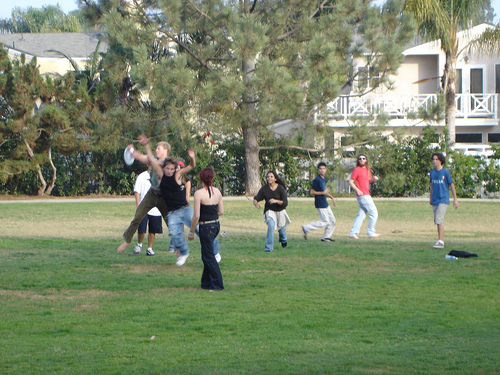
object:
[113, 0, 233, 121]
tree branch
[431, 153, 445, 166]
hair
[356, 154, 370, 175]
hair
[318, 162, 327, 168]
hair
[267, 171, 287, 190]
hair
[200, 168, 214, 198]
hair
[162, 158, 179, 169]
hair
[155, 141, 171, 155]
hair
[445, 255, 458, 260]
bottle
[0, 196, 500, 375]
ground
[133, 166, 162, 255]
man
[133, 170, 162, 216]
white shirt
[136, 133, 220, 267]
boy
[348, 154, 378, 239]
boy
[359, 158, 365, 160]
sunglasses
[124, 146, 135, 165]
frisbee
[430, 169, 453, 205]
blue shirt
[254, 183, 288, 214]
shirt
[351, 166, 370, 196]
red shirt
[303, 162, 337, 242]
guy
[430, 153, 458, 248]
boy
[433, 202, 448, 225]
shorts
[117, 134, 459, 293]
group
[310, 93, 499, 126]
balcony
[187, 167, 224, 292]
girl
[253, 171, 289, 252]
kid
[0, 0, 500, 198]
trees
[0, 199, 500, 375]
grass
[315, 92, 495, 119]
railing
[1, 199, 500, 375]
park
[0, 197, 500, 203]
walkway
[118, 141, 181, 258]
boy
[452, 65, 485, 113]
door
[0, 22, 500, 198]
home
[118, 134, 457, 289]
people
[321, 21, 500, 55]
rooftop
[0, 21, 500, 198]
house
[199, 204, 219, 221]
tube top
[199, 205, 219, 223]
black outfit